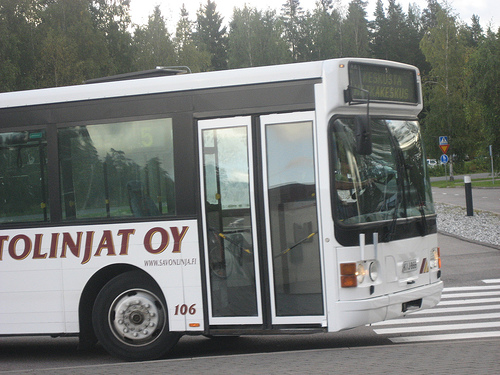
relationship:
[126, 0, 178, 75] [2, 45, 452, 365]
trees behind bus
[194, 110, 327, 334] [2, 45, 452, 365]
door of bus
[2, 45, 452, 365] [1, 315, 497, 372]
bus on road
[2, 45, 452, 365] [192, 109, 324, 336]
bus has doors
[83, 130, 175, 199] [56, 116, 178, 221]
reflection on glass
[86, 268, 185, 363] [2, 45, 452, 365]
tire on bus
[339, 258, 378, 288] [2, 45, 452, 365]
headlights on bus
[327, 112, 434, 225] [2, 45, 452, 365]
windshield on bus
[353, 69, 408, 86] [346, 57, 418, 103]
writing on sign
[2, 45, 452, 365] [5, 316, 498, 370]
bus on roadway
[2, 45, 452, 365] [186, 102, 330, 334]
bus has door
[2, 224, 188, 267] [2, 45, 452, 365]
writing on bus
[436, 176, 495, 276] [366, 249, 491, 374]
path near roadway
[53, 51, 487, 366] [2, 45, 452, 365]
sign on bus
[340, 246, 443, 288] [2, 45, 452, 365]
headlights front bus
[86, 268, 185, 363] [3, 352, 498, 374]
tire on pavement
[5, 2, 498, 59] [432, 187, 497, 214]
trees by road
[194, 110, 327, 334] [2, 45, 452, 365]
door on bus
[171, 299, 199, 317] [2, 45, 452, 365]
number on bus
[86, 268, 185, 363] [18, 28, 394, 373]
tire on bus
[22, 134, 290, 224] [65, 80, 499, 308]
windows on bus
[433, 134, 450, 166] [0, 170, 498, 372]
sign along road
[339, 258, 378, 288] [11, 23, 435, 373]
headlights on bus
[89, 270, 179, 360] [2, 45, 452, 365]
left wheel on bus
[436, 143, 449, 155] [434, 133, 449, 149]
yield sign between sign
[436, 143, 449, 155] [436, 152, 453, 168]
yield sign between sign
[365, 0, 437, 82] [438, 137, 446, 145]
tree beyond sign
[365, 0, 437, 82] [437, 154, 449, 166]
tree beyond sign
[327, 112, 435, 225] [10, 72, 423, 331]
windshield on bus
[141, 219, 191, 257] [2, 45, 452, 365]
oy on bus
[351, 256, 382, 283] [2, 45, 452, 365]
headlights on bus